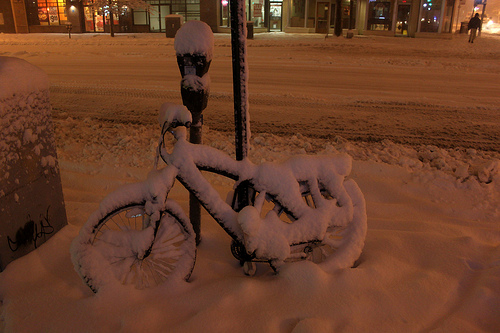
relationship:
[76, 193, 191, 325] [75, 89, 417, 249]
wheel on bicycle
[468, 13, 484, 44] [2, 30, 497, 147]
person on street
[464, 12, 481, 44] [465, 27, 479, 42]
person has legs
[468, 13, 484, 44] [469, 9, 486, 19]
person has head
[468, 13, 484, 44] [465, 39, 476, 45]
person wearing shoes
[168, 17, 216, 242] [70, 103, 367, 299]
meter behind bicycle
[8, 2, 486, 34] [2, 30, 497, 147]
shops that are shown across street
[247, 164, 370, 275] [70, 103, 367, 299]
back wheel of bicycle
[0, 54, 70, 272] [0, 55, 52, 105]
block in snow